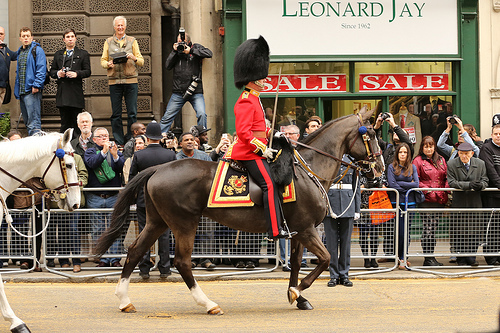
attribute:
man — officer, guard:
[233, 78, 286, 239]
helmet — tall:
[235, 35, 270, 93]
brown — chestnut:
[158, 185, 168, 200]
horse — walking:
[95, 107, 386, 316]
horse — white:
[1, 128, 81, 332]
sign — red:
[357, 73, 448, 93]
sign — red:
[262, 74, 347, 93]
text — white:
[261, 76, 342, 90]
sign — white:
[248, 1, 456, 49]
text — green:
[280, 0, 426, 32]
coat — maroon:
[413, 155, 448, 207]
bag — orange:
[366, 191, 394, 225]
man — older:
[83, 127, 123, 183]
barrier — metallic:
[405, 186, 499, 277]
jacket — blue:
[16, 42, 47, 100]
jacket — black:
[166, 45, 212, 93]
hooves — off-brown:
[121, 284, 300, 315]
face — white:
[46, 155, 84, 212]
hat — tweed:
[458, 143, 477, 153]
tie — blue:
[66, 51, 74, 59]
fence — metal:
[34, 181, 496, 278]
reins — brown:
[285, 134, 382, 176]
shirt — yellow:
[101, 37, 141, 75]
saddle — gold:
[207, 162, 297, 208]